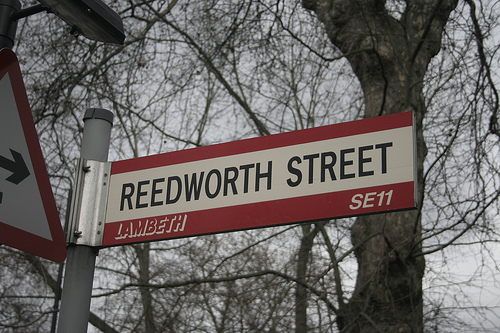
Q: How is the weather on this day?
A: It is cloudy.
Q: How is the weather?
A: It is cloudy.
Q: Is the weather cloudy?
A: Yes, it is cloudy.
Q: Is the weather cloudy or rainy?
A: It is cloudy.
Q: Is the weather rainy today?
A: No, it is cloudy.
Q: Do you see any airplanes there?
A: No, there are no airplanes.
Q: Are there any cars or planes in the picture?
A: No, there are no planes or cars.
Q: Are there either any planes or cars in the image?
A: No, there are no planes or cars.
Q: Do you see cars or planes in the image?
A: No, there are no planes or cars.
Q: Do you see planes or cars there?
A: No, there are no planes or cars.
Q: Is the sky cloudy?
A: Yes, the sky is cloudy.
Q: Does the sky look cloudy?
A: Yes, the sky is cloudy.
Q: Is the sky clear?
A: No, the sky is cloudy.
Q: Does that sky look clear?
A: No, the sky is cloudy.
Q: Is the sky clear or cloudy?
A: The sky is cloudy.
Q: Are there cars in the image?
A: No, there are no cars.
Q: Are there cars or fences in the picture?
A: No, there are no cars or fences.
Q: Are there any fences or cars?
A: No, there are no cars or fences.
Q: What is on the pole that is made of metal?
A: The sign is on the pole.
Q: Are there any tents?
A: No, there are no tents.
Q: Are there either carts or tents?
A: No, there are no tents or carts.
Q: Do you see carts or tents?
A: No, there are no tents or carts.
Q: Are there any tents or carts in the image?
A: No, there are no tents or carts.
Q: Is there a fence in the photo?
A: No, there are no fences.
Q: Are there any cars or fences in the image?
A: No, there are no fences or cars.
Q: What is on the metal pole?
A: The sign is on the pole.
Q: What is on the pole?
A: The sign is on the pole.